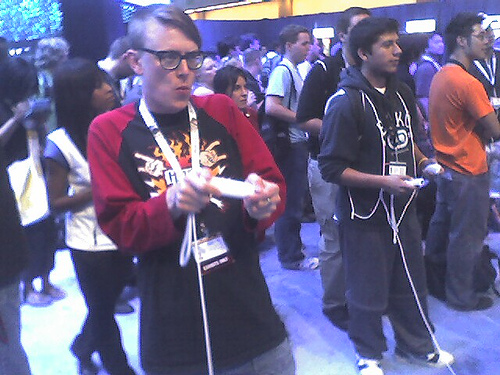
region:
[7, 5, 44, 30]
trees outside the window.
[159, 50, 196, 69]
glasses on boy's face.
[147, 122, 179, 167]
lanyard around boy's neck.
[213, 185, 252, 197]
controller in boy's hand.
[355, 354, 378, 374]
shoe on boy's foot.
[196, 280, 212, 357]
cord connected to controller.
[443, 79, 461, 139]
orange shirt on boy's torso.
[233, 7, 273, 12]
yellow paint on the wall.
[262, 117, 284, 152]
black bag on boy's arm.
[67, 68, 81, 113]
black hair on girl's head.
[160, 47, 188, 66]
black glasses on boy.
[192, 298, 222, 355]
white cord for the controller.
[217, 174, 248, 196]
controller in boy's hand.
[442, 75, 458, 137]
orange t-shirt on boy's torso.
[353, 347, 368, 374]
shoe on boy's foot.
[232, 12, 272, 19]
yellow paint on the wall.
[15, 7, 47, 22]
trees outside the window.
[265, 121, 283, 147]
black bag on boy's shoulder.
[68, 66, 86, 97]
black hair on girl's head.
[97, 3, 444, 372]
Two young men playing Wii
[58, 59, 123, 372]
African American woman on left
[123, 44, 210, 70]
Eyeglasses on man playing Wii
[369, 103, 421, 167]
Writing on black sweatshirt of man playing Wii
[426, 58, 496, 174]
Orange t-shirt on man on right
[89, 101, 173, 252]
red sleeve on right arm of man playing Wii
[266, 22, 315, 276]
man wearing light-colored t-shirt in middle of frame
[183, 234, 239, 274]
ID tag of man wearing red and black shirt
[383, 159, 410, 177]
ID tag of man wearing black sweatshirt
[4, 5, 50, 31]
bit of trees in upper left corner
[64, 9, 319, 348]
a guy holding a wii remote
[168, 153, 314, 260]
a white wii remote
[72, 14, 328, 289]
a guy playing a game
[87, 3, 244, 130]
a guy wearing glasses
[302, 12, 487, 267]
a guy in a black hoodie playing the wii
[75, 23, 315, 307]
a guy wearing a red and white shirt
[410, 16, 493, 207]
a guy wearing an orange shirt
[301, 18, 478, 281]
a guy wearing a black hoodie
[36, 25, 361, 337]
a guy making a face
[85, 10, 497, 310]
two guys playing the wii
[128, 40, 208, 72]
a black pair of glasses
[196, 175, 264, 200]
a white controller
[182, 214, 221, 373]
a white cord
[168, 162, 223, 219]
the hand of a man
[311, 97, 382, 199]
the arm of a man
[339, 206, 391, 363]
the leg of a man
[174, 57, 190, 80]
the nose of a man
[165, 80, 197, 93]
the mouth of a man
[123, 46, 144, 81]
the ear of a man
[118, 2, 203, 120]
the head of a man